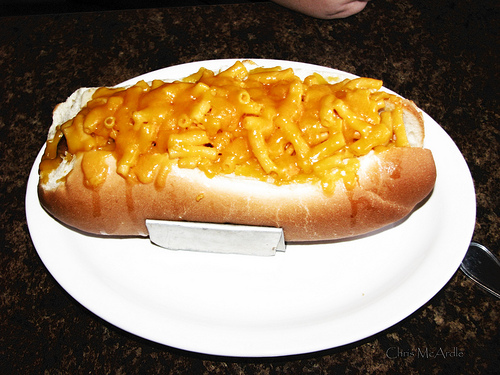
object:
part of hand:
[272, 2, 369, 18]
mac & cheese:
[68, 62, 406, 184]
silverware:
[460, 243, 499, 297]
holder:
[147, 219, 285, 257]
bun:
[40, 147, 434, 243]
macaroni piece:
[248, 126, 276, 173]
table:
[0, 0, 499, 374]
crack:
[304, 205, 310, 232]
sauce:
[126, 185, 133, 213]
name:
[387, 348, 463, 359]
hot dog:
[41, 63, 434, 243]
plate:
[26, 216, 476, 356]